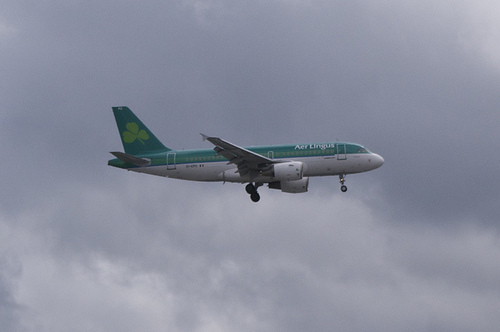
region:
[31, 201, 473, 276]
clouds in the sky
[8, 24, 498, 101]
the sky behind the plane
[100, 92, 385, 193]
a green and white airplane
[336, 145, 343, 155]
a door on the airplane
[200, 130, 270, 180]
a wing on the airplane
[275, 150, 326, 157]
windows on the airplane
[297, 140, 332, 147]
writing on the airplane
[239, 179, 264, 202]
tires on the airplane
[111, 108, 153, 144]
the tail wing on the plane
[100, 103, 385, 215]
an airplane flying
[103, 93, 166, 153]
The back wing of the plane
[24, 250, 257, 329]
The clouds are fluffy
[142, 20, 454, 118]
The sky is the color gray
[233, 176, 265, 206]
The back wheels of the plane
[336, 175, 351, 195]
The front wheel of the plane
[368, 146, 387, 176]
The nose of the airplane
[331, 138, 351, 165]
The door on the airplane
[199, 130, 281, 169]
The wing on the airplane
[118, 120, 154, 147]
A logo on the airplane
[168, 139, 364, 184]
The color of the plane is white and green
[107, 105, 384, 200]
the airplane in the sky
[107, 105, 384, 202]
the airplane in mid air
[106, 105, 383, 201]
the green and white airplane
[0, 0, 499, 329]
the clouds in the sky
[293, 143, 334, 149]
the letters on the side of the plane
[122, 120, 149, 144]
the clover on the tail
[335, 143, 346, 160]
the door on the plane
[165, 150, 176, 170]
the door on the plane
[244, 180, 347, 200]
the wheels under the plane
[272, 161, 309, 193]
the engines on the plane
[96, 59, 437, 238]
A white and green airplane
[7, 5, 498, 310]
An airplane flying in a partly cloudy sky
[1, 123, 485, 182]
A long patch of blue sky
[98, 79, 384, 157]
The top, green half of a green and white plane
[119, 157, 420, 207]
The bottom, white half of a green and white plane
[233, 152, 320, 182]
A white plane engine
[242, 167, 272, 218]
Two landing gear wheels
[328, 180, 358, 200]
One small landing gear wheel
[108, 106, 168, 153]
Light green shamrock logo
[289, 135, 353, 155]
"Aer Lingus" Company Name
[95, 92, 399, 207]
plane flying to the right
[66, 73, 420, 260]
plane in a cloudy sky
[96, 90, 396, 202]
plane is green and white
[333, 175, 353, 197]
front wheel of plane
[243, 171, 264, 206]
back wheels of plane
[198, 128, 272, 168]
left wing of plane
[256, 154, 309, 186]
left engine of plane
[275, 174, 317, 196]
right engine of plane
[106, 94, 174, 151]
vertical stabilizer of plane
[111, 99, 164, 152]
green clover on stabilizer